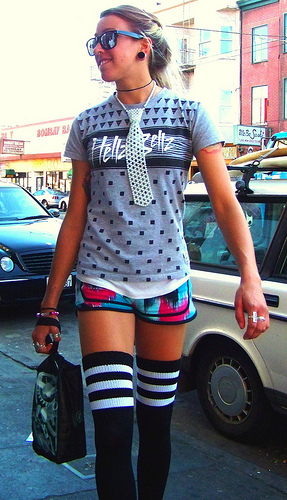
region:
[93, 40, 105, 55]
a nose with a nose ring in it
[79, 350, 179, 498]
black thigh highs with white rings around the top of them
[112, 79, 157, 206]
a white and black tie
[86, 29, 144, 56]
a black pair of refective sunglasses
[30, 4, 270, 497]
a woman with blond hair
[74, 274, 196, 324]
a pair of blue pink and black shorts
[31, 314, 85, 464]
a black hand bag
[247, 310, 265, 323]
a big silver ring on her left index finger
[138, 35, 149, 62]
ear with a stretched out earing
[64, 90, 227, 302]
t-shirt with hellz bellz on it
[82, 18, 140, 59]
large reflective sunglasses on woman's head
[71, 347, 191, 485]
over-the-knee socks with three stripes on top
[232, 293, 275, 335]
silver rings of different shapes on a hand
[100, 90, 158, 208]
tie composed of small white pearlized beads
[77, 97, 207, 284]
grey t-shirt with squares, stripes and triangles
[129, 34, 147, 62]
gold and black button earring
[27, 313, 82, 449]
handle of tote bag wrapped around woman's hand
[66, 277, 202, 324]
colorful shorts with black borders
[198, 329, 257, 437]
car wheel with hubcap of many spokes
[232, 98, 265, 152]
commercial sign perpendicular to building facade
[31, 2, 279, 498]
Girl walking on sidewalk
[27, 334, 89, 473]
Bag being held by girl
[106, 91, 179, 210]
necktie on girl's t-shirt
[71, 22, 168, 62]
Sunglasses on girl's face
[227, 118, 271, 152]
Business sign in background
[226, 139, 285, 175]
surfboards on car in background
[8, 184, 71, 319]
Black car behind girl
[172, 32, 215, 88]
Fire escape behind girl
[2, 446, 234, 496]
Sidewalk girl is walking on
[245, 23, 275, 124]
Building windows behind girl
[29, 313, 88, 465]
a black tote with graphic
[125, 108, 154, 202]
a black and white tie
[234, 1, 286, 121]
an old brick building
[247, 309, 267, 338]
silver colored costume jewelry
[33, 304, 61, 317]
beaded bracelet on wrist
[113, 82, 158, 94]
a cord choker necklace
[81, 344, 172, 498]
long black stockings with white stripes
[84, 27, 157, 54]
sunglasses are reflecting onlookers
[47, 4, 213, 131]
a woman with color treated hair smiles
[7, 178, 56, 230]
multiple automobiles are visible in the background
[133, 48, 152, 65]
Black gauged earring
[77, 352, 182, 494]
Black and white striped socks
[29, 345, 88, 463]
Black and white shopping bag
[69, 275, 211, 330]
Pink, blue and black shorts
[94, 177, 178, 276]
Black and grey shirt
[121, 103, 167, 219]
Black and white tie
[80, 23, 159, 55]
She is wearing black sunglasses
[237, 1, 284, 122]
Red brick building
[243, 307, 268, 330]
Silver ring on her pointer finger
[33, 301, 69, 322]
Two bracelets on her right arm